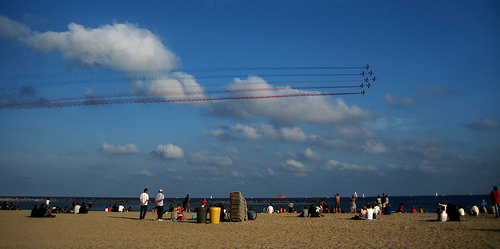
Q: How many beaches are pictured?
A: One.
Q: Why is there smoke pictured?
A: Jets.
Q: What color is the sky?
A: Cloudy.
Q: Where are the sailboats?
A: Beach.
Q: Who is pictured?
A: Visitors.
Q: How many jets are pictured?
A: 6.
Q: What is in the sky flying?
A: Jets.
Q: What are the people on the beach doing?
A: Watching the jet.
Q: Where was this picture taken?
A: The beach.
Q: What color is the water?
A: Blue.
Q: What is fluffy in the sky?
A: Clouds.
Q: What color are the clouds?
A: White.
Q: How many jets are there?
A: 8.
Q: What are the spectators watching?
A: Planes.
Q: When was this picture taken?
A: Daytime.